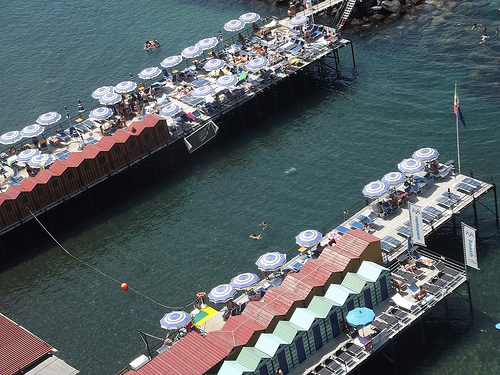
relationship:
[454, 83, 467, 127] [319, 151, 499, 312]
flag on dock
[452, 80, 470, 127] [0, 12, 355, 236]
flag end of dock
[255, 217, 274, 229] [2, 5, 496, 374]
person in water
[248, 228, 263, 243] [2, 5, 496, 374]
person in water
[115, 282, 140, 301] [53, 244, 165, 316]
ball in center of rope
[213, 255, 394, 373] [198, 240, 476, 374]
structures on deck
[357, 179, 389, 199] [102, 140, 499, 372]
umbrella on dock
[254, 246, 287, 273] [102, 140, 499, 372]
umbrella on a dock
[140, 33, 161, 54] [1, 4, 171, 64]
person in water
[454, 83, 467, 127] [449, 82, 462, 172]
flag on a pole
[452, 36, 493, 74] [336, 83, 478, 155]
people swimming in water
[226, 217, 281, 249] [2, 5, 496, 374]
swimmers are having fun in water